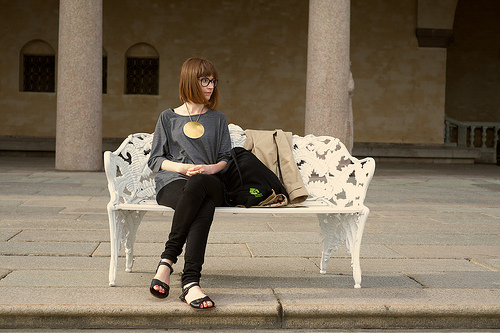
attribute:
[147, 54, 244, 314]
woman — sitting, white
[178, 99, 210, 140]
necklace — big, yellow, gold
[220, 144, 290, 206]
bag — large, black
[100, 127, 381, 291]
bench — white, light, metal, decorative, wide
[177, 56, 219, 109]
hair — brown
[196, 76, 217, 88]
glasses — dark, black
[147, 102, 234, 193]
shirt — long, grey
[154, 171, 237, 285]
pants — dark, black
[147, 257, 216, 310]
shoes — black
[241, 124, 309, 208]
coat — tan, light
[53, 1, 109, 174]
column — tall